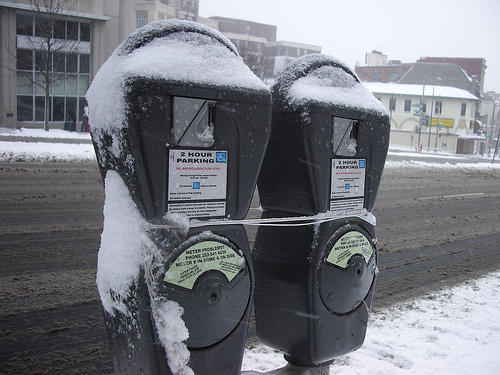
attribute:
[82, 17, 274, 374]
meter — dual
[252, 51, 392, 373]
meter — dual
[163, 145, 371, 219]
stickers — little 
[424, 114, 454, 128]
sign — yellow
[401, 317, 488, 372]
snow — white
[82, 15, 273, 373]
parking meter — black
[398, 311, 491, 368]
snow — muddy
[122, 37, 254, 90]
snow — white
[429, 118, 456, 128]
sign — yellow 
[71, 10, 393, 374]
meter — 2 hour parking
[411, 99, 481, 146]
banner — yellow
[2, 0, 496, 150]
buildings — large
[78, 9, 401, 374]
meters — black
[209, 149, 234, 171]
handicapped sign — blue 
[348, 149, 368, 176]
handicapped sign — blue 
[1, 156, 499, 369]
road — very dirty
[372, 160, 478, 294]
road — black 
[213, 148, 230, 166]
handicap sign — small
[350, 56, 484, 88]
roof — black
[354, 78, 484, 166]
building — white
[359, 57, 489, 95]
roof — brown